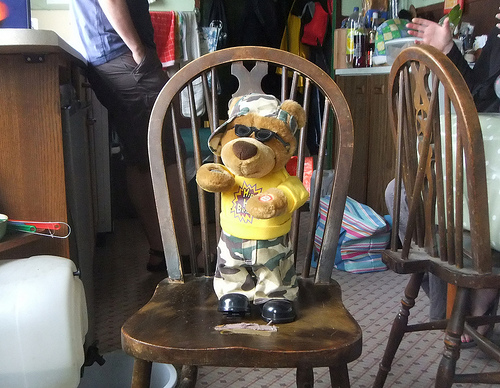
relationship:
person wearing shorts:
[61, 1, 209, 273] [74, 44, 191, 214]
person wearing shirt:
[61, 1, 209, 273] [71, 0, 152, 60]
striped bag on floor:
[302, 188, 394, 276] [314, 263, 486, 385]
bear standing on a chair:
[194, 91, 311, 326] [380, 35, 497, 385]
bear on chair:
[194, 91, 311, 326] [121, 40, 368, 387]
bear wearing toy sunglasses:
[189, 86, 316, 325] [216, 109, 333, 144]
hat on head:
[198, 94, 310, 145] [210, 83, 306, 177]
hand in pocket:
[131, 47, 145, 63] [125, 44, 167, 89]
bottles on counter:
[338, 8, 393, 63] [333, 63, 415, 87]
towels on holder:
[147, 9, 200, 117] [191, 7, 198, 16]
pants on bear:
[213, 225, 304, 318] [189, 86, 316, 325]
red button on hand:
[251, 185, 281, 210] [174, 145, 233, 199]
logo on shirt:
[231, 179, 264, 224] [214, 167, 308, 239]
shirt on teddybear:
[214, 167, 308, 239] [198, 92, 310, 318]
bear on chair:
[194, 91, 311, 326] [121, 40, 439, 372]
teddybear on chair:
[198, 92, 310, 318] [121, 40, 368, 387]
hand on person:
[405, 17, 454, 57] [407, 17, 499, 114]